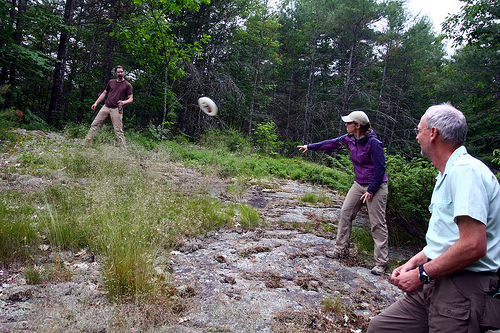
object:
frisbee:
[197, 97, 220, 117]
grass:
[0, 111, 497, 332]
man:
[78, 65, 139, 150]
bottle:
[114, 99, 126, 114]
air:
[179, 175, 347, 325]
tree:
[147, 20, 185, 152]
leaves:
[109, 11, 155, 43]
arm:
[124, 82, 135, 107]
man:
[364, 102, 500, 333]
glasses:
[410, 122, 425, 135]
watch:
[416, 265, 434, 284]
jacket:
[304, 130, 390, 193]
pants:
[322, 184, 390, 276]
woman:
[294, 109, 392, 275]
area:
[0, 111, 497, 333]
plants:
[0, 106, 498, 332]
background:
[0, 1, 499, 333]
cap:
[340, 111, 371, 128]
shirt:
[101, 77, 134, 109]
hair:
[422, 100, 463, 145]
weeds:
[89, 189, 178, 305]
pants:
[80, 105, 128, 148]